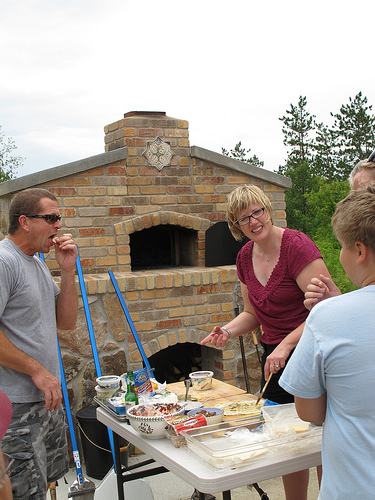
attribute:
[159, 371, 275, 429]
boards — wooden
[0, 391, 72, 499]
pants — camouflage, black, grey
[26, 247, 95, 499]
tool — blue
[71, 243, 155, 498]
tool — blue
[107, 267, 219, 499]
tool — blue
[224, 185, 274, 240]
hair — blond, short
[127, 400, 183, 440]
bowl — white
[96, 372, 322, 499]
table — white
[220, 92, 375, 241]
trees — green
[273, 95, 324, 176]
tree — green, pine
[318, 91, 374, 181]
tree — green, pine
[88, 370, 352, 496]
table — white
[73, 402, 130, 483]
tub — small, gray, yellow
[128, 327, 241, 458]
fireplace — brick, outdoor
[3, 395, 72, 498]
cargo pants — gray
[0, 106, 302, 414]
oven — pizza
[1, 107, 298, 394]
brick oven — background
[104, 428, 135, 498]
leg — black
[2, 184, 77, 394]
man — wearing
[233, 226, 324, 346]
blouse — maroon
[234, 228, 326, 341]
shirt — purple, blue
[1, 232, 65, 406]
shirt — gray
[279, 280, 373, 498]
shirt — white, light blue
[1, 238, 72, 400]
shirt — grey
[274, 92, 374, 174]
trees — clustered, green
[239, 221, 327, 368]
shirt — burgundy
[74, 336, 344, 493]
table — full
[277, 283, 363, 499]
shirt — blue